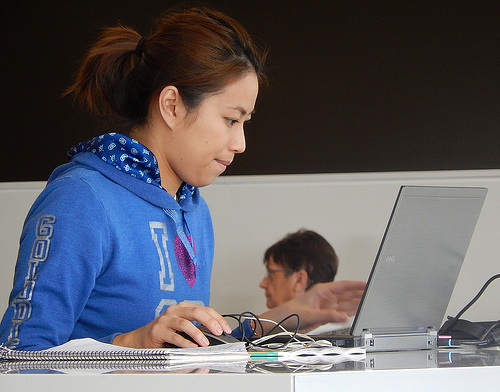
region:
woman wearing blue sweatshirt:
[65, 10, 420, 387]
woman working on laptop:
[62, 57, 497, 367]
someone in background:
[228, 178, 372, 320]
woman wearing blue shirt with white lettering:
[65, 67, 293, 364]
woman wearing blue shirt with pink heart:
[50, 51, 310, 339]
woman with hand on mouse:
[60, 48, 317, 378]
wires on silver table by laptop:
[140, 250, 400, 388]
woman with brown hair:
[41, 47, 393, 342]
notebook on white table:
[27, 247, 267, 389]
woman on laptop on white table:
[34, 57, 491, 369]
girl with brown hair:
[78, 10, 268, 197]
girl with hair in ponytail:
[54, 2, 268, 194]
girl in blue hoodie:
[3, 6, 266, 362]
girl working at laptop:
[0, 11, 490, 358]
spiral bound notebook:
[0, 323, 252, 373]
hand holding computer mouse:
[105, 303, 260, 356]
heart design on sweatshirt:
[168, 223, 204, 292]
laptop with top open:
[252, 174, 494, 353]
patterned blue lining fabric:
[76, 126, 165, 196]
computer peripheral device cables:
[215, 306, 338, 353]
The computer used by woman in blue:
[273, 180, 490, 349]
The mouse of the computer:
[191, 323, 246, 350]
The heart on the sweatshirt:
[173, 231, 202, 286]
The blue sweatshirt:
[0, 128, 215, 364]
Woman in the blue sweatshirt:
[3, 5, 370, 367]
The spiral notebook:
[1, 332, 252, 363]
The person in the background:
[254, 228, 339, 311]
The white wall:
[0, 162, 499, 334]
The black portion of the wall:
[0, 0, 499, 177]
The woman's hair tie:
[133, 33, 150, 60]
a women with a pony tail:
[77, 6, 327, 243]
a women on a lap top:
[70, 32, 457, 377]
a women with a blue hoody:
[45, 21, 257, 347]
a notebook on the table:
[25, 304, 254, 374]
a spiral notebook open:
[30, 310, 263, 367]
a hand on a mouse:
[159, 263, 299, 359]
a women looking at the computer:
[66, 29, 454, 350]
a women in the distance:
[252, 215, 363, 340]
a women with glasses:
[222, 202, 344, 322]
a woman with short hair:
[230, 209, 344, 329]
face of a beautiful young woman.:
[124, 43, 266, 213]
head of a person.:
[236, 209, 366, 321]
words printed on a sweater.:
[137, 208, 205, 334]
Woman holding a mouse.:
[104, 282, 285, 374]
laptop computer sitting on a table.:
[169, 175, 491, 367]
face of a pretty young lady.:
[198, 97, 254, 189]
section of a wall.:
[321, 187, 359, 227]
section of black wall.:
[326, 49, 406, 110]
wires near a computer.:
[226, 300, 301, 359]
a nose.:
[224, 116, 262, 150]